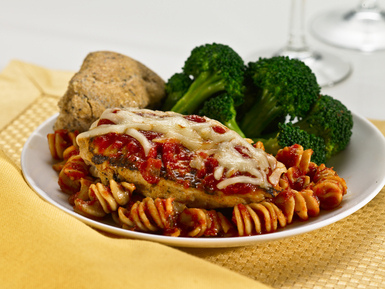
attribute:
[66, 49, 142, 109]
bread — brown, multigrain, served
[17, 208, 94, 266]
placemat — yellow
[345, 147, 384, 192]
plate — round, white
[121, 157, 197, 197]
chicken breast — fried, baked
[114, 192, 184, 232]
pasta — spiral, cooked, cookoed, served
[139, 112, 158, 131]
cheese — melted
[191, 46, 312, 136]
broccoli — green, steamed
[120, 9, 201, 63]
table — white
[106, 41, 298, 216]
dinner — italian, delicious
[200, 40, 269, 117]
vegetable — side, green